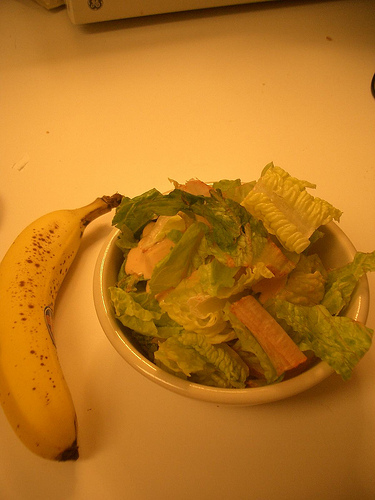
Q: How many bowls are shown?
A: 1.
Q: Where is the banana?
A: Next to the bowl.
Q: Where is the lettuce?
A: In the bowl.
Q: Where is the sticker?
A: On the banana.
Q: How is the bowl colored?
A: White.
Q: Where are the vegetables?
A: In the bowl.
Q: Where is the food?
A: In the bowl.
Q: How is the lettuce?
A: In pieces.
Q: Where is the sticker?
A: On the banana.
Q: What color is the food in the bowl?
A: Green.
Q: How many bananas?
A: One.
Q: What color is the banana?
A: Yellow.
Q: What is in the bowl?
A: Salad.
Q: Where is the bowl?
A: On table.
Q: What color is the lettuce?
A: Green.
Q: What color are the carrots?
A: Orange.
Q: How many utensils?
A: None.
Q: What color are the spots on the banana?
A: Brown.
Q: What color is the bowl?
A: Yellow.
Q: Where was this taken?
A: At a table.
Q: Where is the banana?
A: To the left of the plate.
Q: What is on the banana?
A: Sticker.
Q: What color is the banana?
A: Yellow.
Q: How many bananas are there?
A: 1.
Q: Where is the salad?
A: In the bowl.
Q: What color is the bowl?
A: White.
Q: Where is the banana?
A: Next to the salad.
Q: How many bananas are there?
A: 1.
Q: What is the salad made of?
A: Lettuce.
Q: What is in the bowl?
A: Salad.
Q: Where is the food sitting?
A: On a counter.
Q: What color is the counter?
A: White.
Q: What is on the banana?
A: Spots.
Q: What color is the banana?
A: Yellow.